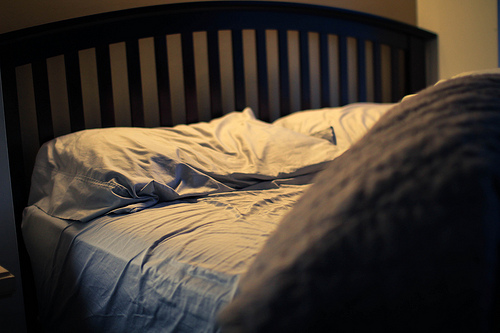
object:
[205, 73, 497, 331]
mass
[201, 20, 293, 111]
wood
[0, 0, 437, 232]
headboard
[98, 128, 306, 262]
wrinkles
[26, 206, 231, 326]
bed side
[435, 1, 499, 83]
wall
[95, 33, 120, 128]
plank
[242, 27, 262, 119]
slat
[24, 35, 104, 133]
wood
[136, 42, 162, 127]
slat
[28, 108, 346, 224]
pillow covers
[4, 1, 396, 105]
walls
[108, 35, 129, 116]
slat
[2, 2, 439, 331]
bed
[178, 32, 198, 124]
slat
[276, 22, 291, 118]
slat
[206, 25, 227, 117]
bar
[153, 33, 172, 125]
bar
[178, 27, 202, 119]
bar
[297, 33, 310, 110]
bar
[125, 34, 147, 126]
bar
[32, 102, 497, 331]
comforter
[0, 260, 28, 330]
nightstand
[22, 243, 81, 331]
shadow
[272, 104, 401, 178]
pillow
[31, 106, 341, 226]
pillow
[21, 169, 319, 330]
bedsheet